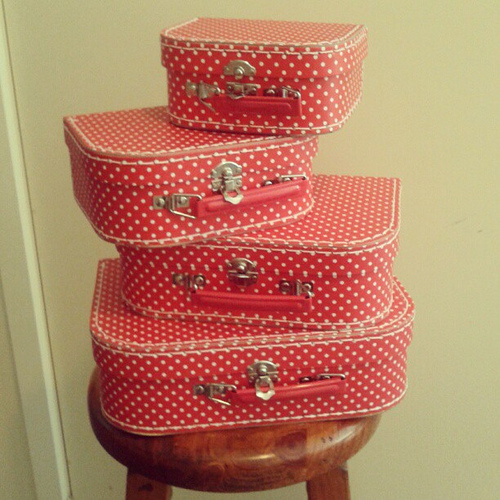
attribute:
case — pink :
[184, 33, 401, 142]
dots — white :
[244, 52, 384, 152]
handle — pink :
[160, 158, 317, 232]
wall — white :
[359, 43, 483, 439]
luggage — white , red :
[79, 45, 406, 479]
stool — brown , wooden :
[125, 416, 412, 488]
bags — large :
[119, 308, 464, 440]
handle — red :
[168, 350, 388, 426]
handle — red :
[194, 268, 311, 317]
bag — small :
[96, 202, 458, 361]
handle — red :
[172, 260, 322, 318]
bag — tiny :
[86, 91, 311, 261]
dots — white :
[121, 136, 244, 268]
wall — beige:
[343, 18, 479, 418]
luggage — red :
[97, 28, 398, 248]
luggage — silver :
[186, 53, 319, 149]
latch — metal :
[218, 54, 258, 82]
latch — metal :
[201, 159, 247, 193]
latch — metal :
[219, 250, 257, 282]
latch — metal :
[242, 351, 278, 407]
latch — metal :
[309, 365, 352, 389]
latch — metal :
[272, 275, 318, 300]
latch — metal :
[157, 262, 221, 291]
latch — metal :
[150, 180, 203, 210]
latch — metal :
[262, 167, 312, 188]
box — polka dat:
[155, 55, 373, 137]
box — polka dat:
[72, 115, 310, 240]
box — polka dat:
[127, 235, 385, 316]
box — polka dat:
[77, 251, 416, 443]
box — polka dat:
[144, 58, 338, 138]